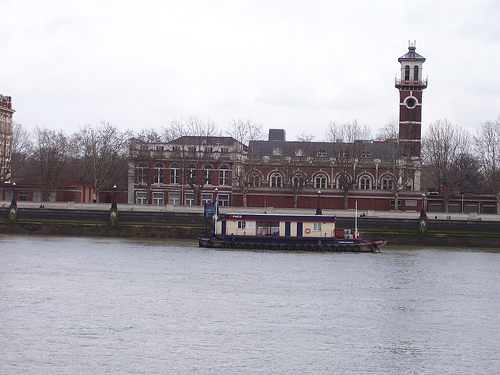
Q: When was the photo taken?
A: Daytime.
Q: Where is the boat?
A: In the water.